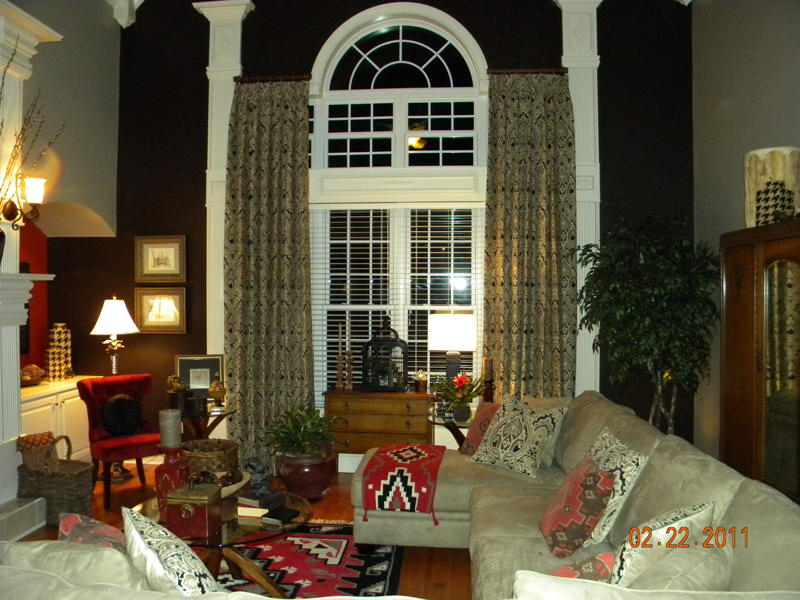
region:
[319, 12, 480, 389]
Lamp reflection in the large window.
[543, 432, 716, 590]
Throw pillows on the sofa.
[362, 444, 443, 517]
Red multi colored throw.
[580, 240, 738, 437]
Indoor potted tree behind sofa.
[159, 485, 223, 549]
Red cube box with gold top.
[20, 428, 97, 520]
Brown weaved basket.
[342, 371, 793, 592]
Beige sofa with pillows.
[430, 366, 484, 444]
Glass table with vase of red flowers.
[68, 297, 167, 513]
Floor lamp behind a red chair.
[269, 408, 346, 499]
Green plant in a brown pot.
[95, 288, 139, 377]
Lamp is on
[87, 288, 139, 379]
Lamp shade is white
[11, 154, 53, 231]
Light globe is shining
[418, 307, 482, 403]
Lamp is on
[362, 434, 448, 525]
Red, white, and black throw on couch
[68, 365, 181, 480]
Red chair is next to lamp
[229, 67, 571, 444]
Curtains on both sides of window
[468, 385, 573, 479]
Throw pillow on couch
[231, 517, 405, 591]
Rug is on floor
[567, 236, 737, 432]
Green tree is in corner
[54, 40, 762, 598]
A large room full of furniture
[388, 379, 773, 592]
A beige sofa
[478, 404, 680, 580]
Beige, black and red pillows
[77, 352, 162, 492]
A red chair with brown legs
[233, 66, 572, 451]
Long brown printed curtains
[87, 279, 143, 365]
A white floor lamp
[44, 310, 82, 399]
Gold colored vases sitting on cabinet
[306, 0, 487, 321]
A white arched window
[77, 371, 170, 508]
red uphostered chair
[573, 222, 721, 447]
large potted plant with green leaves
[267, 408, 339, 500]
potted plant on floor in ceramic dish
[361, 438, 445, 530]
red tapestry throw with geometric patterns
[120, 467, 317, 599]
round glass table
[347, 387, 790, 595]
comfy beige sofa with several patterned cushions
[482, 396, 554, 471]
beige and black patterned cushion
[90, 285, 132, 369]
floor lamp with white lampshade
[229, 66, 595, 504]
window with patterned floor length curtainds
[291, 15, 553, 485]
The window is very tall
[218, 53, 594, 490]
The drapes are green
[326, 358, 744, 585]
The red blanket is on the tan couch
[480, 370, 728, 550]
The tan pillow is on the couch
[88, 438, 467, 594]
The red rug is on the floor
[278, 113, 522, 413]
The blinds are white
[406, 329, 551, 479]
The red flower is on the table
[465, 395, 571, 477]
pillow on the sofa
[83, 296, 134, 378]
lamp in the room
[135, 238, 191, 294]
painting on the wall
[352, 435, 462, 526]
red stool cover with designs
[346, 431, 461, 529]
red stool cover with designs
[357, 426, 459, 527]
red stool cover with designs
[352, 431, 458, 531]
red stool cover with designs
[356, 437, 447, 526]
red stool cover with designs